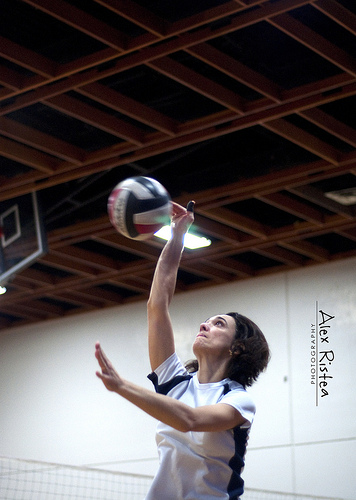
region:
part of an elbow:
[172, 407, 195, 425]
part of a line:
[259, 422, 289, 478]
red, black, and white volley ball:
[102, 176, 170, 240]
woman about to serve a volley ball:
[92, 199, 271, 498]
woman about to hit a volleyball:
[92, 198, 278, 499]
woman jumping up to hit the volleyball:
[93, 201, 268, 499]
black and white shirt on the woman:
[146, 351, 254, 499]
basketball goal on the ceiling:
[0, 190, 54, 281]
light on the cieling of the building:
[153, 228, 212, 252]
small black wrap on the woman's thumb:
[185, 201, 195, 213]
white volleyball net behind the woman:
[0, 454, 347, 498]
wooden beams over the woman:
[0, 0, 350, 332]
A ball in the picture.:
[104, 174, 168, 238]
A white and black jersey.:
[148, 427, 243, 491]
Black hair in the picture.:
[235, 316, 271, 386]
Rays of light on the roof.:
[182, 236, 209, 249]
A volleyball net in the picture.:
[24, 463, 110, 498]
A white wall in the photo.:
[23, 340, 78, 440]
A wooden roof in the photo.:
[188, 47, 317, 192]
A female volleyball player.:
[96, 212, 273, 497]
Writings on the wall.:
[303, 306, 336, 407]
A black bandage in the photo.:
[183, 196, 196, 212]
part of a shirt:
[200, 480, 226, 496]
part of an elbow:
[179, 421, 208, 439]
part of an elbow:
[187, 414, 202, 430]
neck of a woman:
[195, 367, 206, 379]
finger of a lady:
[101, 370, 105, 380]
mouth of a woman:
[207, 346, 222, 363]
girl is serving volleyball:
[100, 178, 173, 249]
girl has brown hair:
[199, 280, 269, 381]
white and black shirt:
[129, 330, 252, 481]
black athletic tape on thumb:
[182, 199, 203, 216]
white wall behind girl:
[45, 359, 100, 429]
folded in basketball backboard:
[0, 196, 75, 302]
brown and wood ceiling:
[33, 177, 304, 299]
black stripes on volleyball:
[107, 181, 163, 231]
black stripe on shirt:
[149, 356, 201, 409]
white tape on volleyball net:
[4, 455, 109, 498]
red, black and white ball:
[105, 177, 170, 241]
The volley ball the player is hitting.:
[105, 178, 172, 239]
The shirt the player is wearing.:
[144, 354, 247, 498]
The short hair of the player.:
[217, 308, 268, 385]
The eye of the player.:
[215, 320, 224, 327]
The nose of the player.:
[199, 321, 206, 330]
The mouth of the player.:
[195, 333, 207, 337]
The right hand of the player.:
[93, 343, 120, 390]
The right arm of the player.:
[117, 378, 232, 433]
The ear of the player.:
[228, 339, 245, 355]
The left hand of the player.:
[169, 201, 194, 229]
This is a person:
[94, 165, 281, 495]